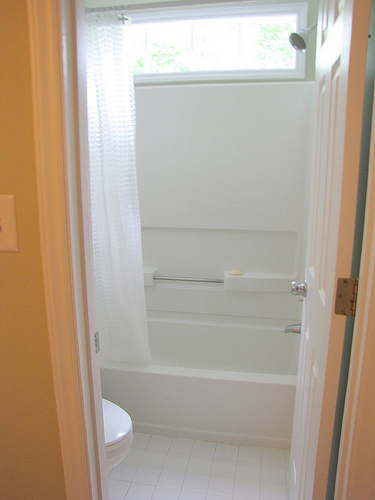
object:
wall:
[0, 0, 64, 498]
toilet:
[99, 396, 134, 481]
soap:
[227, 268, 243, 276]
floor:
[103, 428, 287, 497]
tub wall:
[126, 361, 287, 446]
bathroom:
[86, 0, 338, 494]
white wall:
[150, 91, 294, 226]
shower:
[120, 21, 319, 445]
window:
[135, 3, 306, 89]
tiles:
[154, 462, 190, 493]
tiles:
[201, 471, 237, 498]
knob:
[287, 278, 309, 297]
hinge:
[334, 276, 358, 317]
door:
[276, 1, 358, 498]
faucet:
[282, 322, 300, 336]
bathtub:
[102, 309, 298, 447]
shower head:
[289, 21, 317, 55]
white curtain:
[79, 9, 153, 364]